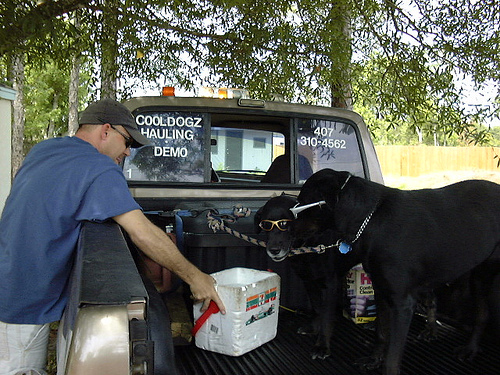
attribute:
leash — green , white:
[206, 210, 323, 265]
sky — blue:
[121, 4, 496, 122]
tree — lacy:
[227, 5, 441, 117]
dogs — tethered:
[253, 157, 489, 364]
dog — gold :
[290, 167, 498, 373]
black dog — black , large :
[253, 195, 440, 360]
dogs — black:
[231, 176, 496, 340]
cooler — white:
[192, 267, 284, 357]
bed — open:
[127, 196, 498, 373]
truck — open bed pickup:
[55, 94, 499, 374]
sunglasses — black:
[119, 131, 136, 149]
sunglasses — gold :
[257, 213, 294, 233]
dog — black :
[249, 192, 449, 362]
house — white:
[216, 128, 277, 173]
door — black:
[223, 129, 250, 176]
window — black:
[252, 134, 269, 152]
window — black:
[207, 131, 219, 152]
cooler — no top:
[169, 245, 277, 368]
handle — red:
[189, 296, 221, 338]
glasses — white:
[260, 211, 294, 225]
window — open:
[208, 112, 300, 191]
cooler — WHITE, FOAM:
[163, 251, 295, 373]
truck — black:
[108, 100, 422, 371]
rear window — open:
[210, 115, 288, 192]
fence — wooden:
[374, 130, 494, 172]